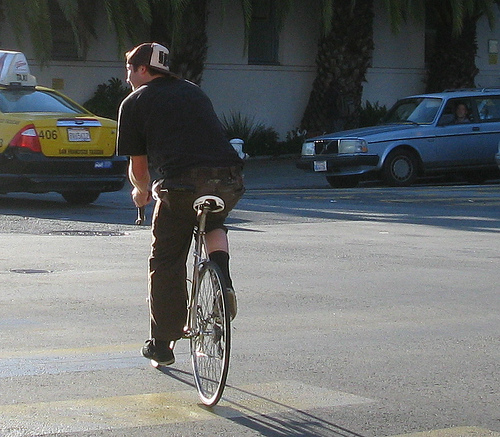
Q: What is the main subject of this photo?
A: Man riding a bike.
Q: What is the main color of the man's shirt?
A: Black.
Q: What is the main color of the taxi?
A: Yellow.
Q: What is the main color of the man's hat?
A: Black and white.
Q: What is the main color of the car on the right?
A: Blue.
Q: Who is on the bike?
A: A man in black.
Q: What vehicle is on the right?
A: A blue one.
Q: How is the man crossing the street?
A: In the crosswalk.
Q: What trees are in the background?
A: Palm tree.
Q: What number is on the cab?
A: 406.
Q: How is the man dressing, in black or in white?
A: Black.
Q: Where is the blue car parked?
A: On the road.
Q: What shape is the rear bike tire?
A: Circle.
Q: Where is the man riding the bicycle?
A: Street.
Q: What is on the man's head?
A: Hat.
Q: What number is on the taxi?
A: 406.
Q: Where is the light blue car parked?
A: Street.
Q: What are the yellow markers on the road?
A: Crosswalk.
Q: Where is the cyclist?
A: Crosswalk.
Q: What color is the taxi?
A: Yellow.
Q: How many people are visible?
A: Two.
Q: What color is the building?
A: White.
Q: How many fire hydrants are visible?
A: One.